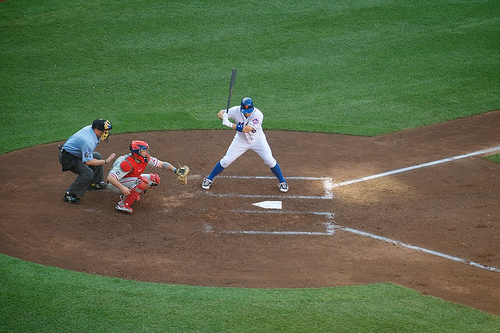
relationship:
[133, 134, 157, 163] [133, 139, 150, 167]
mask on face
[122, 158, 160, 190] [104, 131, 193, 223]
guard on catcher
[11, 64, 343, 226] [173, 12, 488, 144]
people on field